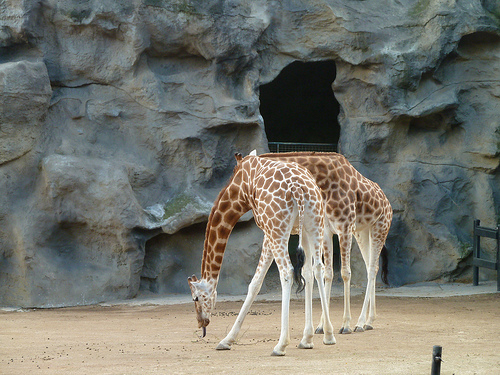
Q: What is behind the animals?
A: A rock wall.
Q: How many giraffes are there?
A: 2.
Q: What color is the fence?
A: Black.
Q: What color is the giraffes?
A: Brown and White.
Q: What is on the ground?
A: Brown.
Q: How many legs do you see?
A: 8.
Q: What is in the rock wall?
A: A large hole.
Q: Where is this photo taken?
A: In the zoo.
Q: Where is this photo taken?
A: At the zoo.